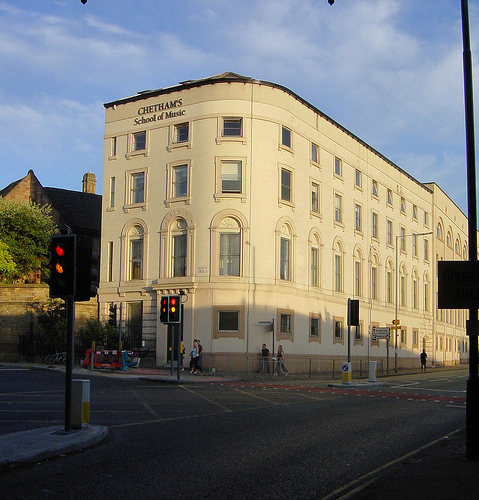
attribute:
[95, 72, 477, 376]
building — tan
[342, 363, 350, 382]
box — electronic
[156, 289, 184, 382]
stop light — yellow, red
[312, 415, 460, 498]
line — yellow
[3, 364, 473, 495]
street — empty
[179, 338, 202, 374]
people — beside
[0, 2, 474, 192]
sky — blue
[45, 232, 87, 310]
stop light — red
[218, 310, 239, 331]
window — small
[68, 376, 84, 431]
box — metal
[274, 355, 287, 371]
pants — gray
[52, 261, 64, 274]
light — orange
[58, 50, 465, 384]
building — large, white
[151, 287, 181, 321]
light — red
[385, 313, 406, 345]
sign — bright, yellow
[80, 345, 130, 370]
barrier — red, white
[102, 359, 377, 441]
lines — yellow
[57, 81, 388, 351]
building — large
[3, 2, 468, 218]
sky — blue, clear